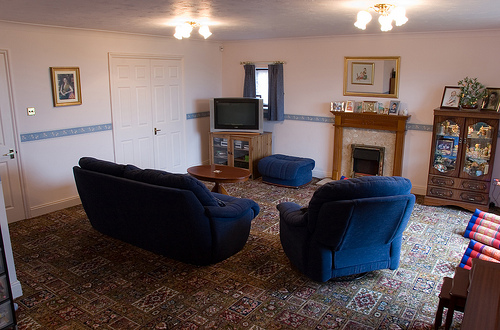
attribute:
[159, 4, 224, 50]
lights — on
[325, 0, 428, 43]
lights — on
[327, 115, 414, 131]
mantel — brown, wood, wooden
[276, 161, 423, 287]
chair — blue, upholstered, reclining, rocking, dark blue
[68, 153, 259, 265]
couch — blue, dark blue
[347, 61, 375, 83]
picture — reflecting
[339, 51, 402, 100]
mirror — framed, wood, gold framed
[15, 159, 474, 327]
carpet — multi color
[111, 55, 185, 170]
doors — white, panel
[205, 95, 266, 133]
tv — silver, black, flat screen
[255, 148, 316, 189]
ottoman — blue, dark blue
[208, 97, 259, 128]
television — silver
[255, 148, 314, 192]
footstool — blue, upholstered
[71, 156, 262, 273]
love seat — blue, upholstered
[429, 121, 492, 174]
door — glass, whte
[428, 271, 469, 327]
side tables — wood, nesting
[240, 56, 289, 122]
curtains — blue, window, dark blue, pair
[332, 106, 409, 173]
fireplace — white, stone, here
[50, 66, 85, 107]
picture — framed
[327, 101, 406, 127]
mantle — brown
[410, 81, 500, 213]
curio cabinet — brown, wood, wooden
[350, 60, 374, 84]
reflection — print, framed print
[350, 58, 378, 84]
print — framed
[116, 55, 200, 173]
double doors — white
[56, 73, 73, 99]
photograph — woman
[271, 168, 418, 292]
recliner — dark blue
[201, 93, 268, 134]
television — flat screen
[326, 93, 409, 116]
items — framed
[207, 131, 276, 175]
tv cabinet — wood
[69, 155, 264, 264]
living room sofa — blue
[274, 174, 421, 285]
living room chair — blue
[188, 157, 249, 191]
coffee table — brown, wooden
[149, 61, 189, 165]
door — white